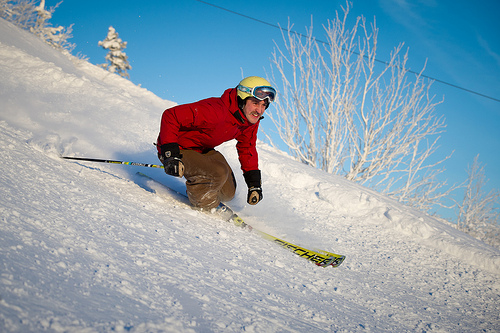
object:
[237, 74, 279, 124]
head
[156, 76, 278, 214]
man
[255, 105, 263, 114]
nose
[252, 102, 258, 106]
eye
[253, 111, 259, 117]
mouth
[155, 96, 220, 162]
arm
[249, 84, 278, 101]
pair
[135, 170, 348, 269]
pair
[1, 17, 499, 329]
snow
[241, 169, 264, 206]
glove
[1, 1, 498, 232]
sky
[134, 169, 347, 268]
skis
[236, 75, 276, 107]
helmet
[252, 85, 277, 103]
goggles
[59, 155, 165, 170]
pole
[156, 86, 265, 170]
coat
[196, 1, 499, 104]
cord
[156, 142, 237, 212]
pants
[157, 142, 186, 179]
gloves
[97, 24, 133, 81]
ice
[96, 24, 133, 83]
tree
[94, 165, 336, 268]
ski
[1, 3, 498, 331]
skiing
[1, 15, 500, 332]
hillside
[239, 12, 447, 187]
tree